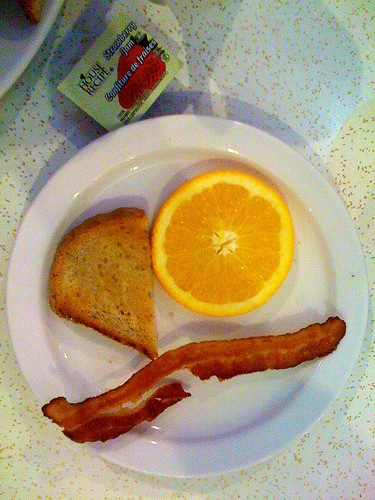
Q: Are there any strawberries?
A: Yes, there is a strawberry.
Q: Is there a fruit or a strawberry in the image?
A: Yes, there is a strawberry.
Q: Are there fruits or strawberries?
A: Yes, there is a strawberry.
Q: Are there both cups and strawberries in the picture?
A: No, there is a strawberry but no cups.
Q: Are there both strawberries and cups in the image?
A: No, there is a strawberry but no cups.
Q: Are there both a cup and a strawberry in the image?
A: No, there is a strawberry but no cups.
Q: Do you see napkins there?
A: No, there are no napkins.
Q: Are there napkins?
A: No, there are no napkins.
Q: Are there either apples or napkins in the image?
A: No, there are no napkins or apples.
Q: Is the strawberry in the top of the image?
A: Yes, the strawberry is in the top of the image.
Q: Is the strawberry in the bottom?
A: No, the strawberry is in the top of the image.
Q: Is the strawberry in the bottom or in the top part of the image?
A: The strawberry is in the top of the image.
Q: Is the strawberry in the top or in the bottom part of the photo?
A: The strawberry is in the top of the image.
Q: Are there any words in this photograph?
A: Yes, there are words.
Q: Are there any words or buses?
A: Yes, there are words.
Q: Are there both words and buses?
A: No, there are words but no buses.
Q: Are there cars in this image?
A: No, there are no cars.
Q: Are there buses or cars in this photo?
A: No, there are no cars or buses.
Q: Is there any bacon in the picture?
A: Yes, there is bacon.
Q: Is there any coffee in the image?
A: No, there is no coffee.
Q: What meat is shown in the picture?
A: The meat is bacon.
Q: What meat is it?
A: The meat is bacon.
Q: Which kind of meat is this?
A: This is bacon.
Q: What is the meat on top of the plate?
A: The meat is bacon.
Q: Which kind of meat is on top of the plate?
A: The meat is bacon.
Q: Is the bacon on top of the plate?
A: Yes, the bacon is on top of the plate.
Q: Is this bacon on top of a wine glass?
A: No, the bacon is on top of the plate.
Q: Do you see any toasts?
A: Yes, there is a toast.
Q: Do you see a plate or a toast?
A: Yes, there is a toast.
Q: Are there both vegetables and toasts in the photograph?
A: No, there is a toast but no vegetables.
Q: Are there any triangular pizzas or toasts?
A: Yes, there is a triangular toast.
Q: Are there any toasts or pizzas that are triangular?
A: Yes, the toast is triangular.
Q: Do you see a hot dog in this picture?
A: No, there are no hot dogs.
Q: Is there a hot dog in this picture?
A: No, there are no hot dogs.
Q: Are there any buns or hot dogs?
A: No, there are no hot dogs or buns.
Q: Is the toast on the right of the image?
A: No, the toast is on the left of the image.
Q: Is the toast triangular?
A: Yes, the toast is triangular.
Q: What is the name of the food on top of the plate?
A: The food is a toast.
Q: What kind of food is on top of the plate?
A: The food is a toast.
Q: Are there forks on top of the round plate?
A: No, there is a toast on top of the plate.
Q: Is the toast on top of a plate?
A: Yes, the toast is on top of a plate.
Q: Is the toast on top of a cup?
A: No, the toast is on top of a plate.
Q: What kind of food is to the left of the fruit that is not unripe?
A: The food is a toast.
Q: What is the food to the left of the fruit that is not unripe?
A: The food is a toast.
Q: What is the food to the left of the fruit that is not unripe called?
A: The food is a toast.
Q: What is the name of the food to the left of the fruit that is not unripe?
A: The food is a toast.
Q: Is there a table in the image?
A: Yes, there is a table.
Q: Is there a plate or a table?
A: Yes, there is a table.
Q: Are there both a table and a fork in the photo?
A: No, there is a table but no forks.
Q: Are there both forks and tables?
A: No, there is a table but no forks.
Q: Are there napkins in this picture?
A: No, there are no napkins.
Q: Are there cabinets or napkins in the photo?
A: No, there are no napkins or cabinets.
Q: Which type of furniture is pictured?
A: The furniture is a table.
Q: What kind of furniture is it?
A: The piece of furniture is a table.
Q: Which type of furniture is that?
A: This is a table.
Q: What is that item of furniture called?
A: This is a table.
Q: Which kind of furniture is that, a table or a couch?
A: This is a table.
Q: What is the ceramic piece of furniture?
A: The piece of furniture is a table.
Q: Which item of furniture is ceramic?
A: The piece of furniture is a table.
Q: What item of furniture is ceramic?
A: The piece of furniture is a table.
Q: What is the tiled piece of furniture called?
A: The piece of furniture is a table.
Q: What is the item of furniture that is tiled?
A: The piece of furniture is a table.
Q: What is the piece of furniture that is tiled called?
A: The piece of furniture is a table.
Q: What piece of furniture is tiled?
A: The piece of furniture is a table.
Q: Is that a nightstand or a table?
A: That is a table.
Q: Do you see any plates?
A: Yes, there is a plate.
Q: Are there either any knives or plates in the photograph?
A: Yes, there is a plate.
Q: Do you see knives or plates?
A: Yes, there is a plate.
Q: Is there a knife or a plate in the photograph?
A: Yes, there is a plate.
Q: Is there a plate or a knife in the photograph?
A: Yes, there is a plate.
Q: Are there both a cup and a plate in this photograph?
A: No, there is a plate but no cups.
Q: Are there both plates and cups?
A: No, there is a plate but no cups.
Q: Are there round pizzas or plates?
A: Yes, there is a round plate.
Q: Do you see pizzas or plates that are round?
A: Yes, the plate is round.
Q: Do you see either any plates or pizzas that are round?
A: Yes, the plate is round.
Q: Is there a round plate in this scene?
A: Yes, there is a round plate.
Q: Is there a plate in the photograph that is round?
A: Yes, there is a plate that is round.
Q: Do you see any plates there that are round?
A: Yes, there is a plate that is round.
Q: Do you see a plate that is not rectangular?
A: Yes, there is a round plate.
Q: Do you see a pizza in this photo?
A: No, there are no pizzas.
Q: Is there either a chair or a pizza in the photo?
A: No, there are no pizzas or chairs.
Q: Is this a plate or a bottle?
A: This is a plate.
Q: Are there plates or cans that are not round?
A: No, there is a plate but it is round.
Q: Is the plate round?
A: Yes, the plate is round.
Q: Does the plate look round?
A: Yes, the plate is round.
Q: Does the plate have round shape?
A: Yes, the plate is round.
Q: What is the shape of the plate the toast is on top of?
A: The plate is round.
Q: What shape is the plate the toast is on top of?
A: The plate is round.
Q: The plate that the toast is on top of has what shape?
A: The plate is round.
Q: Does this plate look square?
A: No, the plate is round.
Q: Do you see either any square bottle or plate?
A: No, there is a plate but it is round.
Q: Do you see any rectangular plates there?
A: No, there is a plate but it is round.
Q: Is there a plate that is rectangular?
A: No, there is a plate but it is round.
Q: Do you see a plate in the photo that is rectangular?
A: No, there is a plate but it is round.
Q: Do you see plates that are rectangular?
A: No, there is a plate but it is round.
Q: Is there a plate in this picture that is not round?
A: No, there is a plate but it is round.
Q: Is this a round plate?
A: Yes, this is a round plate.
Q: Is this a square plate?
A: No, this is a round plate.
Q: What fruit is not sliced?
A: The fruit is a strawberry.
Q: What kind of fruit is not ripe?
A: The fruit is a strawberry.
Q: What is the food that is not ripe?
A: The food is a strawberry.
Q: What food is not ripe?
A: The food is a strawberry.